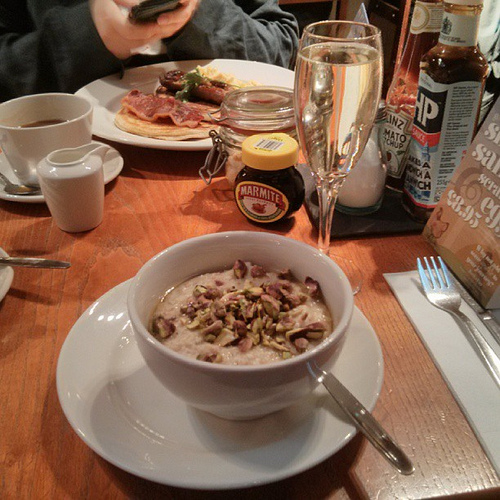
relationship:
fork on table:
[416, 255, 499, 393] [1, 99, 498, 500]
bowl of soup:
[127, 230, 355, 424] [149, 260, 334, 363]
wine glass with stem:
[294, 19, 383, 296] [314, 189, 338, 260]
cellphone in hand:
[130, 0, 178, 23] [89, 0, 160, 60]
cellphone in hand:
[130, 0, 178, 23] [154, 0, 201, 40]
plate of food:
[73, 58, 295, 148] [113, 64, 260, 141]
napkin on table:
[381, 269, 499, 481] [1, 99, 498, 500]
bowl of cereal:
[127, 230, 355, 424] [149, 260, 334, 363]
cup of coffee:
[0, 91, 92, 188] [11, 119, 69, 128]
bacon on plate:
[121, 88, 203, 126] [73, 58, 295, 148]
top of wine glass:
[300, 20, 383, 47] [294, 19, 383, 296]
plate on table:
[73, 58, 295, 148] [1, 99, 498, 500]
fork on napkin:
[416, 255, 499, 393] [381, 269, 499, 481]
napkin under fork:
[381, 269, 499, 481] [416, 255, 499, 393]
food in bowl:
[149, 260, 334, 363] [127, 230, 355, 424]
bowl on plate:
[127, 230, 355, 424] [56, 277, 383, 491]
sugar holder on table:
[197, 88, 295, 191] [1, 99, 498, 500]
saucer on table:
[0, 139, 125, 201] [1, 99, 498, 500]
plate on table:
[56, 277, 383, 491] [1, 99, 498, 500]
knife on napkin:
[445, 264, 499, 346] [381, 269, 499, 481]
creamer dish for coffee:
[36, 142, 109, 232] [11, 119, 69, 128]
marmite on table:
[232, 131, 305, 227] [1, 99, 498, 500]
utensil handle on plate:
[3, 258, 73, 268] [0, 244, 14, 302]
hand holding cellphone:
[89, 0, 160, 60] [130, 0, 178, 23]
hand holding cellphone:
[154, 0, 201, 40] [130, 0, 178, 23]